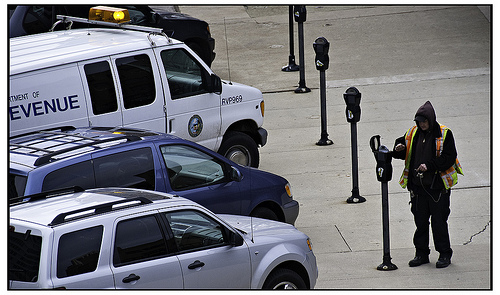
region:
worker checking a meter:
[334, 40, 476, 278]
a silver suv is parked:
[174, 216, 316, 281]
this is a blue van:
[183, 138, 297, 196]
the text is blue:
[9, 90, 91, 132]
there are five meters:
[272, 37, 434, 270]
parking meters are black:
[278, 48, 431, 269]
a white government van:
[21, 22, 343, 201]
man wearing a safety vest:
[351, 52, 498, 216]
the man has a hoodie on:
[349, 56, 490, 228]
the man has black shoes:
[339, 55, 474, 292]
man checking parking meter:
[368, 100, 462, 287]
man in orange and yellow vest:
[390, 91, 461, 238]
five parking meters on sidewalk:
[283, 3, 411, 229]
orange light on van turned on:
[25, 1, 172, 54]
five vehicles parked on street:
[10, 8, 302, 292]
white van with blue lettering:
[5, 22, 266, 157]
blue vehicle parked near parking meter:
[14, 118, 336, 229]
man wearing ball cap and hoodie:
[395, 73, 461, 254]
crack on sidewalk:
[444, 158, 493, 262]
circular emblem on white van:
[175, 91, 224, 157]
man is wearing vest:
[448, 171, 461, 182]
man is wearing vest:
[456, 167, 461, 187]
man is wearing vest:
[400, 157, 416, 182]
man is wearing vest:
[446, 174, 455, 186]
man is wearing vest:
[441, 180, 467, 187]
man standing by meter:
[378, 100, 463, 264]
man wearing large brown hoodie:
[375, 91, 497, 271]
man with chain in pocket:
[414, 170, 454, 211]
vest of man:
[380, 126, 465, 205]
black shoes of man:
[412, 236, 452, 271]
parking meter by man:
[317, 80, 374, 207]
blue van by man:
[0, 139, 297, 212]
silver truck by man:
[0, 210, 352, 293]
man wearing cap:
[372, 94, 462, 273]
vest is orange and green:
[400, 122, 472, 198]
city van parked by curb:
[11, 12, 265, 174]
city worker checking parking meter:
[391, 99, 462, 269]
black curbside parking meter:
[343, 84, 370, 207]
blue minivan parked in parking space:
[10, 132, 300, 221]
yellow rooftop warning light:
[89, 4, 131, 26]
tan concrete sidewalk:
[198, 8, 494, 293]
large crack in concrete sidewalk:
[463, 213, 488, 246]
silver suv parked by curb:
[7, 185, 320, 294]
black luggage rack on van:
[9, 121, 144, 167]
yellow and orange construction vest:
[399, 122, 464, 189]